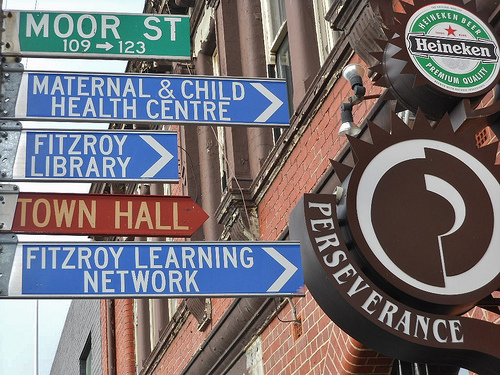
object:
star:
[443, 24, 456, 36]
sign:
[404, 3, 499, 94]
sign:
[366, 0, 498, 133]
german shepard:
[414, 9, 492, 87]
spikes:
[366, 118, 393, 145]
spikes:
[368, 50, 388, 63]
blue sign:
[25, 130, 180, 180]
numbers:
[61, 38, 147, 53]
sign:
[0, 69, 292, 128]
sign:
[0, 9, 193, 61]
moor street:
[25, 13, 182, 42]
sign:
[0, 239, 307, 299]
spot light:
[337, 62, 379, 134]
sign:
[287, 106, 500, 373]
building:
[50, 0, 499, 374]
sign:
[0, 191, 212, 238]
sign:
[0, 131, 178, 179]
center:
[29, 28, 424, 330]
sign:
[0, 128, 180, 185]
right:
[206, 0, 499, 374]